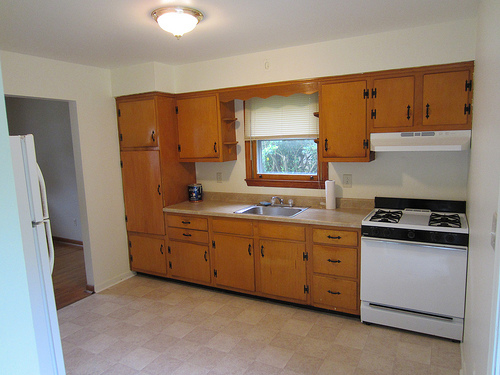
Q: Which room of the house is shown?
A: It is a kitchen.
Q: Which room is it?
A: It is a kitchen.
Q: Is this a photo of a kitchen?
A: Yes, it is showing a kitchen.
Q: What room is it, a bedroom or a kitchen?
A: It is a kitchen.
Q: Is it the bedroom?
A: No, it is the kitchen.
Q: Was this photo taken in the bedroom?
A: No, the picture was taken in the kitchen.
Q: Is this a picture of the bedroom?
A: No, the picture is showing the kitchen.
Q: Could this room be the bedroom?
A: No, it is the kitchen.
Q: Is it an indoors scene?
A: Yes, it is indoors.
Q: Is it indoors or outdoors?
A: It is indoors.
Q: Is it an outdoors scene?
A: No, it is indoors.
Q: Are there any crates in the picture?
A: No, there are no crates.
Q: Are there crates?
A: No, there are no crates.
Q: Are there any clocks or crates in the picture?
A: No, there are no crates or clocks.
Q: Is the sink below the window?
A: Yes, the sink is below the window.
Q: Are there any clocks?
A: No, there are no clocks.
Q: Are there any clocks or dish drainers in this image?
A: No, there are no clocks or dish drainers.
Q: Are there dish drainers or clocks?
A: No, there are no clocks or dish drainers.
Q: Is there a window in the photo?
A: Yes, there is a window.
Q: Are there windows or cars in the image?
A: Yes, there is a window.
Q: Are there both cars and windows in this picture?
A: No, there is a window but no cars.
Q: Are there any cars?
A: No, there are no cars.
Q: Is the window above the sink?
A: Yes, the window is above the sink.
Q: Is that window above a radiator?
A: No, the window is above the sink.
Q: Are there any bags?
A: No, there are no bags.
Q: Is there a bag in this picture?
A: No, there are no bags.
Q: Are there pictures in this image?
A: No, there are no pictures.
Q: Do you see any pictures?
A: No, there are no pictures.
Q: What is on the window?
A: The blinds are on the window.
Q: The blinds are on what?
A: The blinds are on the window.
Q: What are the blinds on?
A: The blinds are on the window.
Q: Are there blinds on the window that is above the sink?
A: Yes, there are blinds on the window.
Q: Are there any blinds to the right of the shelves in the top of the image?
A: Yes, there are blinds to the right of the shelves.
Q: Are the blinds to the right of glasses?
A: No, the blinds are to the right of the shelves.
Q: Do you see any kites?
A: No, there are no kites.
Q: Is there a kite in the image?
A: No, there are no kites.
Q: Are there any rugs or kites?
A: No, there are no kites or rugs.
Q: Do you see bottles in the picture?
A: No, there are no bottles.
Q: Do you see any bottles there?
A: No, there are no bottles.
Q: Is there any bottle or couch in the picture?
A: No, there are no bottles or couches.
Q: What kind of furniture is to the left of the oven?
A: The piece of furniture is a drawer.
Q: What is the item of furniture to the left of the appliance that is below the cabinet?
A: The piece of furniture is a drawer.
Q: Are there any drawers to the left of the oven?
A: Yes, there is a drawer to the left of the oven.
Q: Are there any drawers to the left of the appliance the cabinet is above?
A: Yes, there is a drawer to the left of the oven.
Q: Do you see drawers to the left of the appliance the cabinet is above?
A: Yes, there is a drawer to the left of the oven.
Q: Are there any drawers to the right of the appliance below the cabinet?
A: No, the drawer is to the left of the oven.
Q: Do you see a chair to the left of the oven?
A: No, there is a drawer to the left of the oven.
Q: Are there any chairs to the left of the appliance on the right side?
A: No, there is a drawer to the left of the oven.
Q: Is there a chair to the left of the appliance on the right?
A: No, there is a drawer to the left of the oven.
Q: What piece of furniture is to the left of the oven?
A: The piece of furniture is a drawer.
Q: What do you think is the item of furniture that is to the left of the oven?
A: The piece of furniture is a drawer.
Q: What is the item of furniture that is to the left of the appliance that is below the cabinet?
A: The piece of furniture is a drawer.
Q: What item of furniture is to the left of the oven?
A: The piece of furniture is a drawer.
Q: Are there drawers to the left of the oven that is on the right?
A: Yes, there is a drawer to the left of the oven.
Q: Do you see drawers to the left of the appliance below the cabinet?
A: Yes, there is a drawer to the left of the oven.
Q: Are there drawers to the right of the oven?
A: No, the drawer is to the left of the oven.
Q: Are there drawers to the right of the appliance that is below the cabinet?
A: No, the drawer is to the left of the oven.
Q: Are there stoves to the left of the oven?
A: No, there is a drawer to the left of the oven.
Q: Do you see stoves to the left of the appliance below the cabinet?
A: No, there is a drawer to the left of the oven.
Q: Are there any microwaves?
A: No, there are no microwaves.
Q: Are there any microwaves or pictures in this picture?
A: No, there are no microwaves or pictures.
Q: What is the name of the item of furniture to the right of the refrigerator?
A: The piece of furniture is a drawer.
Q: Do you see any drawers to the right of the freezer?
A: Yes, there is a drawer to the right of the freezer.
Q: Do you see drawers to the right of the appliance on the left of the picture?
A: Yes, there is a drawer to the right of the freezer.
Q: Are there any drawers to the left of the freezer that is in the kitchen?
A: No, the drawer is to the right of the refrigerator.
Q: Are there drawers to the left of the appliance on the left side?
A: No, the drawer is to the right of the refrigerator.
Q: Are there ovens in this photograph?
A: Yes, there is an oven.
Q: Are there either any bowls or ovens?
A: Yes, there is an oven.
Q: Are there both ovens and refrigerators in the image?
A: Yes, there are both an oven and a refrigerator.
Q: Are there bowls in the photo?
A: No, there are no bowls.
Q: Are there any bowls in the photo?
A: No, there are no bowls.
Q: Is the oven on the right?
A: Yes, the oven is on the right of the image.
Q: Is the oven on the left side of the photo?
A: No, the oven is on the right of the image.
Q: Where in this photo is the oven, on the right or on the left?
A: The oven is on the right of the image.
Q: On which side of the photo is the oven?
A: The oven is on the right of the image.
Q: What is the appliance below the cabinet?
A: The appliance is an oven.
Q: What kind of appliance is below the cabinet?
A: The appliance is an oven.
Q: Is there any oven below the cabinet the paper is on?
A: Yes, there is an oven below the cabinet.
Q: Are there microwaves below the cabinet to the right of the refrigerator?
A: No, there is an oven below the cabinet.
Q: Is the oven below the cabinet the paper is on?
A: Yes, the oven is below the cabinet.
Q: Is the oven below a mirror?
A: No, the oven is below the cabinet.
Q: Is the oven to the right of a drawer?
A: Yes, the oven is to the right of a drawer.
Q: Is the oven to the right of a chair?
A: No, the oven is to the right of a drawer.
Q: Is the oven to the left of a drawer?
A: No, the oven is to the right of a drawer.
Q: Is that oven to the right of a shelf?
A: No, the oven is to the right of a drawer.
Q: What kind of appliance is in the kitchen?
A: The appliance is an oven.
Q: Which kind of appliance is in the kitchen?
A: The appliance is an oven.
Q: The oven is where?
A: The oven is in the kitchen.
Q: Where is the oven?
A: The oven is in the kitchen.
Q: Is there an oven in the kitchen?
A: Yes, there is an oven in the kitchen.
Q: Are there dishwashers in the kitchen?
A: No, there is an oven in the kitchen.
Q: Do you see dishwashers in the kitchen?
A: No, there is an oven in the kitchen.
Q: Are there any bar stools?
A: No, there are no bar stools.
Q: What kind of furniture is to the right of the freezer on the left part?
A: The piece of furniture is a drawer.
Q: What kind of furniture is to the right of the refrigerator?
A: The piece of furniture is a drawer.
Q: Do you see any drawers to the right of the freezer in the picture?
A: Yes, there is a drawer to the right of the freezer.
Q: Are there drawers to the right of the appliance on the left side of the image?
A: Yes, there is a drawer to the right of the freezer.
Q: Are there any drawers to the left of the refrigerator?
A: No, the drawer is to the right of the refrigerator.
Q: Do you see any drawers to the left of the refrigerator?
A: No, the drawer is to the right of the refrigerator.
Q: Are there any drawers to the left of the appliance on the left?
A: No, the drawer is to the right of the refrigerator.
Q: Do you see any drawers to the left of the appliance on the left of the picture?
A: No, the drawer is to the right of the refrigerator.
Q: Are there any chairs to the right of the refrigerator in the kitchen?
A: No, there is a drawer to the right of the freezer.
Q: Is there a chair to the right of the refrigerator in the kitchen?
A: No, there is a drawer to the right of the freezer.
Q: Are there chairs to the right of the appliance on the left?
A: No, there is a drawer to the right of the freezer.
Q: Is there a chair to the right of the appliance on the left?
A: No, there is a drawer to the right of the freezer.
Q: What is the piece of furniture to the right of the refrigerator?
A: The piece of furniture is a drawer.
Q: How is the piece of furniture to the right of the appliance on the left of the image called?
A: The piece of furniture is a drawer.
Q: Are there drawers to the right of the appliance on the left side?
A: Yes, there is a drawer to the right of the fridge.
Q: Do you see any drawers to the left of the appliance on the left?
A: No, the drawer is to the right of the fridge.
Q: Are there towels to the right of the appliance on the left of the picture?
A: No, there is a drawer to the right of the freezer.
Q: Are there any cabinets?
A: Yes, there is a cabinet.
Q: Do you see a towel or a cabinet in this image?
A: Yes, there is a cabinet.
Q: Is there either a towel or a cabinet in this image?
A: Yes, there is a cabinet.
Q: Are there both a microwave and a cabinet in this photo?
A: No, there is a cabinet but no microwaves.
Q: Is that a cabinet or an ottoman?
A: That is a cabinet.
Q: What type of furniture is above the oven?
A: The piece of furniture is a cabinet.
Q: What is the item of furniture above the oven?
A: The piece of furniture is a cabinet.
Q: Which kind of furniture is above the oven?
A: The piece of furniture is a cabinet.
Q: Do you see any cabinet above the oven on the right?
A: Yes, there is a cabinet above the oven.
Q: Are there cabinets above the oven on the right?
A: Yes, there is a cabinet above the oven.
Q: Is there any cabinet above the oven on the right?
A: Yes, there is a cabinet above the oven.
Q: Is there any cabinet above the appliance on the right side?
A: Yes, there is a cabinet above the oven.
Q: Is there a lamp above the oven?
A: No, there is a cabinet above the oven.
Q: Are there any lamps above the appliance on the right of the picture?
A: No, there is a cabinet above the oven.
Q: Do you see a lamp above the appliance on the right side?
A: No, there is a cabinet above the oven.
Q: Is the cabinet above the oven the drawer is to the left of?
A: Yes, the cabinet is above the oven.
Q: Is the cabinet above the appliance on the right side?
A: Yes, the cabinet is above the oven.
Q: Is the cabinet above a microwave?
A: No, the cabinet is above the oven.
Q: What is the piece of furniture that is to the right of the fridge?
A: The piece of furniture is a cabinet.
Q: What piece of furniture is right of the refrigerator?
A: The piece of furniture is a cabinet.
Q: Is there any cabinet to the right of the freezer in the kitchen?
A: Yes, there is a cabinet to the right of the refrigerator.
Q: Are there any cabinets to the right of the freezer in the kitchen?
A: Yes, there is a cabinet to the right of the refrigerator.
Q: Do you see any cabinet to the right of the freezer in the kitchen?
A: Yes, there is a cabinet to the right of the refrigerator.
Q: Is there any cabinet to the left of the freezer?
A: No, the cabinet is to the right of the freezer.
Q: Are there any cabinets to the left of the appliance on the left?
A: No, the cabinet is to the right of the freezer.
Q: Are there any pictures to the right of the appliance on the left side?
A: No, there is a cabinet to the right of the freezer.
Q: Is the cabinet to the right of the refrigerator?
A: Yes, the cabinet is to the right of the refrigerator.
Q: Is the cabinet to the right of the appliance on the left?
A: Yes, the cabinet is to the right of the refrigerator.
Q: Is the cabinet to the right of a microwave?
A: No, the cabinet is to the right of the refrigerator.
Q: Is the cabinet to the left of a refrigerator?
A: No, the cabinet is to the right of a refrigerator.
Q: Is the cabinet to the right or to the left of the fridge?
A: The cabinet is to the right of the fridge.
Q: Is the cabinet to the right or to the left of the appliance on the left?
A: The cabinet is to the right of the fridge.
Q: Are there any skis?
A: No, there are no skis.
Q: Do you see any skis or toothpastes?
A: No, there are no skis or toothpastes.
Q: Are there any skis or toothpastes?
A: No, there are no skis or toothpastes.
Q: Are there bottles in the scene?
A: No, there are no bottles.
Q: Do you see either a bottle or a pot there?
A: No, there are no bottles or pots.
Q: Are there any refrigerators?
A: Yes, there is a refrigerator.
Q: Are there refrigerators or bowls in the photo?
A: Yes, there is a refrigerator.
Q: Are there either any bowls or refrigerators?
A: Yes, there is a refrigerator.